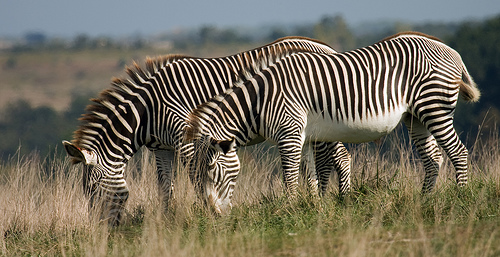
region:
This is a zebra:
[165, 36, 495, 231]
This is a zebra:
[57, 35, 347, 253]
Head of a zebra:
[48, 129, 132, 254]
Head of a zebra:
[172, 95, 263, 229]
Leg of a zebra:
[431, 108, 493, 212]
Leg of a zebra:
[407, 102, 448, 223]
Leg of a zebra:
[334, 128, 368, 200]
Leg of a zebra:
[308, 133, 335, 211]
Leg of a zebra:
[280, 108, 308, 209]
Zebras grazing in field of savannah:
[10, 20, 495, 251]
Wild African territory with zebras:
[18, 19, 485, 231]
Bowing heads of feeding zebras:
[43, 31, 255, 242]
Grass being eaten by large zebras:
[7, 184, 477, 249]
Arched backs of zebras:
[137, 3, 431, 94]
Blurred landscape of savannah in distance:
[2, 13, 358, 128]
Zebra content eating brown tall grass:
[183, 33, 490, 233]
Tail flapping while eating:
[399, 25, 486, 120]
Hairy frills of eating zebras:
[50, 20, 301, 177]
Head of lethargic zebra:
[177, 95, 252, 232]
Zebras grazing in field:
[21, 23, 489, 252]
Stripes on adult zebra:
[268, 68, 388, 120]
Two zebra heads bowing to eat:
[56, 32, 255, 255]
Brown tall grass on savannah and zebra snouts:
[41, 189, 441, 255]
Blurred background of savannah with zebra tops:
[7, 15, 491, 129]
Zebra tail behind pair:
[436, 40, 489, 112]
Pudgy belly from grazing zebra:
[305, 91, 413, 152]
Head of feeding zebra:
[171, 98, 258, 226]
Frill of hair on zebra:
[63, 39, 197, 169]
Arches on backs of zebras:
[180, 23, 435, 102]